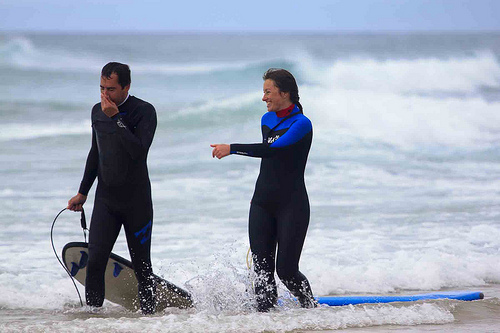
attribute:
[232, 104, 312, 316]
wetsuit — blue, black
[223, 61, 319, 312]
wet suit — blue, black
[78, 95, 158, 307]
wet suit — black, blue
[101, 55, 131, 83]
hair — black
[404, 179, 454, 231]
water — large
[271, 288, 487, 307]
surfboard — blue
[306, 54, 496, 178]
waves — white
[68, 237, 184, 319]
body board — Black and white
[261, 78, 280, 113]
face — smiling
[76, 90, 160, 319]
wetsuit — black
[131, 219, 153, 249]
stripes — blue